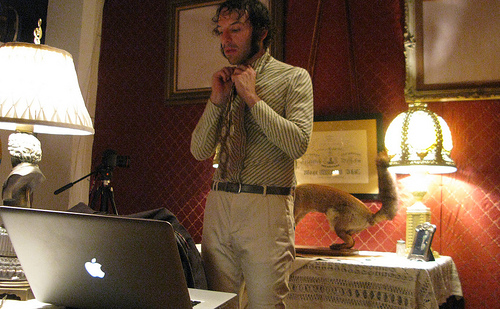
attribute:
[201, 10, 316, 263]
man — looking, ready, standing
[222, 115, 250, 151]
tie — patterned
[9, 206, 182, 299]
laptop — apple, on, grey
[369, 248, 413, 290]
table cloth — old, white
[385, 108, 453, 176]
lamp — gold, on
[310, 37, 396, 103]
wall — red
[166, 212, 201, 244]
luggage — brown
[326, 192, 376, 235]
cat — stuffed, behind